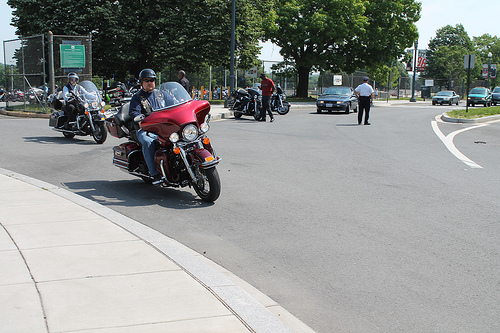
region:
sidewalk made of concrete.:
[95, 280, 154, 305]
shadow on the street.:
[108, 182, 148, 199]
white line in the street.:
[449, 138, 473, 180]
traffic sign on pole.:
[465, 53, 471, 110]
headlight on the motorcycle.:
[184, 122, 197, 145]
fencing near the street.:
[12, 48, 36, 105]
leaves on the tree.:
[174, 23, 212, 42]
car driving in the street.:
[318, 88, 348, 112]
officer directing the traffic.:
[350, 75, 376, 121]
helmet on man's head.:
[137, 66, 155, 81]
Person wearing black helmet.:
[136, 64, 157, 81]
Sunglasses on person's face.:
[133, 70, 163, 91]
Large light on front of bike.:
[179, 118, 224, 165]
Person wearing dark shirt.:
[111, 89, 158, 126]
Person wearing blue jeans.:
[132, 128, 178, 182]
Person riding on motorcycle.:
[128, 130, 205, 197]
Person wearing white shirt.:
[348, 83, 382, 108]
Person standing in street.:
[341, 83, 378, 150]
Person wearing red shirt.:
[261, 70, 281, 102]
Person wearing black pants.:
[249, 98, 283, 124]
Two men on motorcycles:
[36, 36, 235, 222]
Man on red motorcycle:
[101, 52, 251, 223]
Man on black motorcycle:
[30, 43, 130, 153]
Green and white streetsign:
[35, 20, 107, 85]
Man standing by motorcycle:
[216, 48, 304, 134]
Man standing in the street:
[334, 62, 421, 149]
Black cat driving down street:
[296, 52, 371, 122]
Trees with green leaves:
[48, 3, 420, 123]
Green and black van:
[457, 70, 497, 112]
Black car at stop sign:
[416, 72, 463, 115]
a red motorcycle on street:
[105, 82, 221, 203]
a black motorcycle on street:
[49, 79, 106, 144]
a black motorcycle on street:
[222, 86, 266, 121]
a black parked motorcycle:
[270, 84, 291, 114]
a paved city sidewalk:
[0, 166, 284, 330]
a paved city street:
[2, 112, 499, 330]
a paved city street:
[220, 98, 470, 124]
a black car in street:
[315, 82, 355, 114]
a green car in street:
[428, 89, 458, 104]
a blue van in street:
[466, 87, 490, 105]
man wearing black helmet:
[125, 52, 170, 109]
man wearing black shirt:
[86, 50, 241, 195]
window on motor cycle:
[150, 75, 191, 110]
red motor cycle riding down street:
[85, 46, 261, 208]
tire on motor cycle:
[185, 140, 230, 210]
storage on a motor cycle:
[100, 142, 140, 182]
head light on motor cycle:
[178, 120, 214, 153]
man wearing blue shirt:
[337, 65, 397, 155]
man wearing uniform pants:
[350, 73, 376, 133]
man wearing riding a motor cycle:
[50, 59, 107, 144]